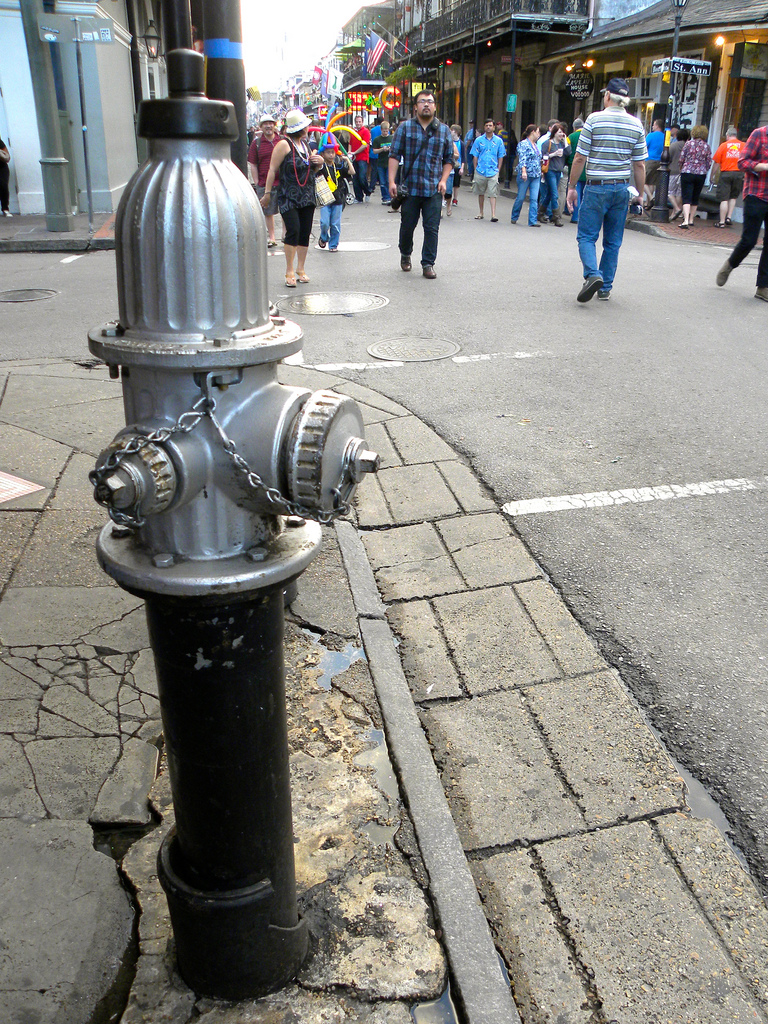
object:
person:
[469, 118, 507, 222]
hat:
[284, 107, 314, 138]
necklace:
[288, 137, 314, 189]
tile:
[360, 521, 469, 608]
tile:
[431, 509, 545, 594]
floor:
[0, 173, 767, 1023]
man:
[562, 76, 651, 311]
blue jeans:
[576, 172, 631, 291]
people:
[387, 79, 455, 283]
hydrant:
[90, 39, 381, 1009]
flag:
[367, 31, 389, 75]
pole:
[376, 21, 412, 53]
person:
[563, 68, 644, 304]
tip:
[137, 46, 243, 139]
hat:
[257, 110, 278, 126]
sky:
[237, 0, 407, 138]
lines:
[526, 841, 614, 1020]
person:
[677, 124, 717, 230]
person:
[710, 123, 752, 232]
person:
[511, 124, 544, 228]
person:
[263, 99, 328, 294]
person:
[312, 134, 357, 252]